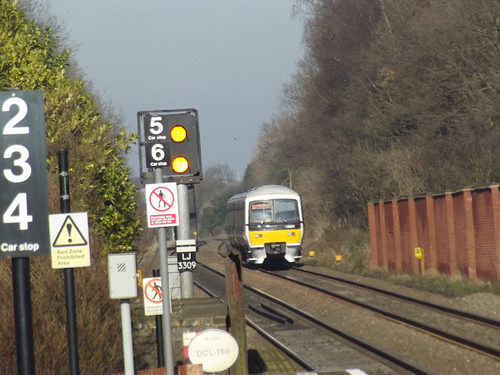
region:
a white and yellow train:
[223, 182, 305, 270]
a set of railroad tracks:
[258, 252, 497, 360]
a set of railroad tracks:
[189, 259, 424, 373]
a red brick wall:
[368, 184, 497, 289]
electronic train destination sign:
[247, 201, 269, 209]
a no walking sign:
[142, 278, 162, 318]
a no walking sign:
[141, 183, 176, 230]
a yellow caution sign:
[46, 215, 91, 269]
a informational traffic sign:
[0, 89, 44, 257]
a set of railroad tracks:
[185, 327, 240, 374]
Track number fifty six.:
[144, 113, 169, 168]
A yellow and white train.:
[224, 184, 303, 264]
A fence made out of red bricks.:
[367, 183, 499, 289]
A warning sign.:
[46, 213, 91, 269]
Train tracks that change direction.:
[246, 301, 294, 323]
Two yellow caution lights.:
[167, 123, 187, 173]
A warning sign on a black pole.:
[46, 145, 90, 373]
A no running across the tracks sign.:
[145, 182, 179, 226]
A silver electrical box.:
[103, 252, 138, 373]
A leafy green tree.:
[1, 1, 142, 255]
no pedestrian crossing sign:
[146, 183, 181, 373]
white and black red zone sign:
[48, 211, 98, 373]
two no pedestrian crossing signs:
[141, 183, 181, 374]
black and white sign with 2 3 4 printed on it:
[1, 88, 48, 374]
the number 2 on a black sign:
[0, 96, 34, 139]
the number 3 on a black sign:
[1, 142, 36, 184]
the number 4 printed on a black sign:
[1, 191, 43, 232]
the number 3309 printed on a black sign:
[176, 259, 199, 270]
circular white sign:
[190, 325, 240, 372]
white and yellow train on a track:
[223, 183, 307, 267]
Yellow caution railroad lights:
[143, 112, 200, 179]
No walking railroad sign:
[142, 182, 179, 228]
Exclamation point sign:
[47, 212, 90, 269]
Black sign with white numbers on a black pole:
[0, 89, 52, 374]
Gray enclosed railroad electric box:
[104, 250, 148, 374]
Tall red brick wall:
[366, 186, 498, 282]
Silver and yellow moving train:
[227, 180, 305, 268]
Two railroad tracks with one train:
[144, 230, 499, 372]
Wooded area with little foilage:
[242, 3, 498, 253]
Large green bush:
[1, 0, 146, 266]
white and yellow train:
[217, 176, 317, 264]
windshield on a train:
[242, 198, 300, 232]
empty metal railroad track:
[186, 254, 372, 371]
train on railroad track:
[222, 172, 494, 337]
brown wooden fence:
[359, 190, 499, 295]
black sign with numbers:
[0, 88, 50, 244]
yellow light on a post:
[164, 119, 194, 146]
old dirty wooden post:
[217, 243, 267, 370]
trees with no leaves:
[292, 12, 497, 144]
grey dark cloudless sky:
[85, 5, 285, 105]